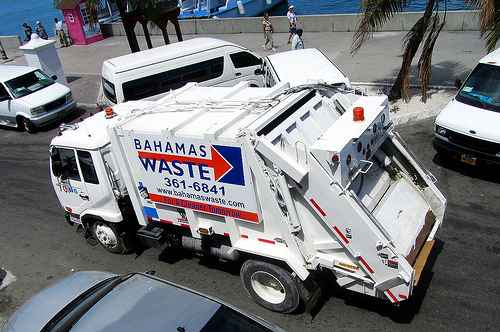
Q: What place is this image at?
A: It is at the street.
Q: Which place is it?
A: It is a street.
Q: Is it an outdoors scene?
A: Yes, it is outdoors.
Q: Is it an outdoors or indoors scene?
A: It is outdoors.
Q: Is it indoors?
A: No, it is outdoors.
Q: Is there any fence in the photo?
A: No, there are no fences.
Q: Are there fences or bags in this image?
A: No, there are no fences or bags.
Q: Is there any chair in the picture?
A: No, there are no chairs.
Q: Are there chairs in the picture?
A: No, there are no chairs.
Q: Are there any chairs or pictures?
A: No, there are no chairs or pictures.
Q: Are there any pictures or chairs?
A: No, there are no chairs or pictures.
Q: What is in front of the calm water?
A: The wall is in front of the water.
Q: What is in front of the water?
A: The wall is in front of the water.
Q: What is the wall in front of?
A: The wall is in front of the water.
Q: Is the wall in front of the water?
A: Yes, the wall is in front of the water.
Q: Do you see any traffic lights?
A: No, there are no traffic lights.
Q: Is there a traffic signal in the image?
A: No, there are no traffic lights.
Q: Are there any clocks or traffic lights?
A: No, there are no traffic lights or clocks.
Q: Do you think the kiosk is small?
A: Yes, the kiosk is small.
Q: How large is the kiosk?
A: The kiosk is small.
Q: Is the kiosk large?
A: No, the kiosk is small.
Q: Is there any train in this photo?
A: No, there are no trains.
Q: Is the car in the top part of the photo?
A: No, the car is in the bottom of the image.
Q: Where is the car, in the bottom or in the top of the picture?
A: The car is in the bottom of the image.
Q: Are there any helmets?
A: No, there are no helmets.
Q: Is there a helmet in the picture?
A: No, there are no helmets.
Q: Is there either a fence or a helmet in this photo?
A: No, there are no helmets or fences.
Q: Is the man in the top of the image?
A: Yes, the man is in the top of the image.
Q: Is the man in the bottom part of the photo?
A: No, the man is in the top of the image.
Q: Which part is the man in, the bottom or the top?
A: The man is in the top of the image.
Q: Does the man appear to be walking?
A: Yes, the man is walking.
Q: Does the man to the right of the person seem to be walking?
A: Yes, the man is walking.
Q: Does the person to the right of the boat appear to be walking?
A: Yes, the man is walking.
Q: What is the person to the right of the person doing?
A: The man is walking.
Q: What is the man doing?
A: The man is walking.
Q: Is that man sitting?
A: No, the man is walking.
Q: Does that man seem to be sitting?
A: No, the man is walking.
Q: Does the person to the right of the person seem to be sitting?
A: No, the man is walking.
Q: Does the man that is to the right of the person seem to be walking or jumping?
A: The man is walking.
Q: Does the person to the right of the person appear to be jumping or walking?
A: The man is walking.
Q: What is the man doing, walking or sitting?
A: The man is walking.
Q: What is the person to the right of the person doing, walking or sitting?
A: The man is walking.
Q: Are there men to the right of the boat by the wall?
A: Yes, there is a man to the right of the boat.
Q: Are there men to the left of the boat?
A: No, the man is to the right of the boat.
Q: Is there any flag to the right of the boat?
A: No, there is a man to the right of the boat.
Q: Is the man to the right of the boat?
A: Yes, the man is to the right of the boat.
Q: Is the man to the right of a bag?
A: No, the man is to the right of the boat.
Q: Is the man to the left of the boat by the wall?
A: No, the man is to the right of the boat.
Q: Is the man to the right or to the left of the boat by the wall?
A: The man is to the right of the boat.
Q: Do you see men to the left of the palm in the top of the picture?
A: Yes, there is a man to the left of the palm.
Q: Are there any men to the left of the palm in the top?
A: Yes, there is a man to the left of the palm.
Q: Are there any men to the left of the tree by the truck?
A: Yes, there is a man to the left of the palm.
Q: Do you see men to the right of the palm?
A: No, the man is to the left of the palm.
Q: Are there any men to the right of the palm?
A: No, the man is to the left of the palm.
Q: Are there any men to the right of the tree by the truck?
A: No, the man is to the left of the palm.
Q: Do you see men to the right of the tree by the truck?
A: No, the man is to the left of the palm.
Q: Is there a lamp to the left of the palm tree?
A: No, there is a man to the left of the palm tree.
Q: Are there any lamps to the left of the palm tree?
A: No, there is a man to the left of the palm tree.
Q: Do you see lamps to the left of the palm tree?
A: No, there is a man to the left of the palm tree.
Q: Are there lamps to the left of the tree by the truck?
A: No, there is a man to the left of the palm tree.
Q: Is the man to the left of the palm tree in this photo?
A: Yes, the man is to the left of the palm tree.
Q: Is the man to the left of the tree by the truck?
A: Yes, the man is to the left of the palm tree.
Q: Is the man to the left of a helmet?
A: No, the man is to the left of the palm tree.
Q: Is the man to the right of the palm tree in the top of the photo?
A: No, the man is to the left of the palm tree.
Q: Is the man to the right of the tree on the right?
A: No, the man is to the left of the palm tree.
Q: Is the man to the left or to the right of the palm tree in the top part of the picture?
A: The man is to the left of the palm.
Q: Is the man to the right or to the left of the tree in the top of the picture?
A: The man is to the left of the palm.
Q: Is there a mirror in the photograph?
A: Yes, there is a mirror.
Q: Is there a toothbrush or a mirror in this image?
A: Yes, there is a mirror.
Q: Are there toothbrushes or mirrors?
A: Yes, there is a mirror.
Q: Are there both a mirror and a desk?
A: No, there is a mirror but no desks.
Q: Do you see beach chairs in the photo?
A: No, there are no beach chairs.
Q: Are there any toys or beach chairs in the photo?
A: No, there are no beach chairs or toys.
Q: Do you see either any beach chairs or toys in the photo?
A: No, there are no beach chairs or toys.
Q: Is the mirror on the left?
A: Yes, the mirror is on the left of the image.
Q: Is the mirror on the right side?
A: No, the mirror is on the left of the image.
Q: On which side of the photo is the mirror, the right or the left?
A: The mirror is on the left of the image.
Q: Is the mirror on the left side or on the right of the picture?
A: The mirror is on the left of the image.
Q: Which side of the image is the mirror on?
A: The mirror is on the left of the image.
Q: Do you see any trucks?
A: Yes, there is a truck.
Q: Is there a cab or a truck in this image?
A: Yes, there is a truck.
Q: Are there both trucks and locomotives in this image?
A: No, there is a truck but no locomotives.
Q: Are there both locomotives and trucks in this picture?
A: No, there is a truck but no locomotives.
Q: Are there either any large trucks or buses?
A: Yes, there is a large truck.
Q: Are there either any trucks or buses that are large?
A: Yes, the truck is large.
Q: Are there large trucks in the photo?
A: Yes, there is a large truck.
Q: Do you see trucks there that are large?
A: Yes, there is a truck that is large.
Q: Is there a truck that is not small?
A: Yes, there is a large truck.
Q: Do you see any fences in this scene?
A: No, there are no fences.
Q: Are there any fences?
A: No, there are no fences.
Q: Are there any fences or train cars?
A: No, there are no fences or train cars.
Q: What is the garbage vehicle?
A: The vehicle is a truck.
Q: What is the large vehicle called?
A: The vehicle is a truck.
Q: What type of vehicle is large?
A: The vehicle is a truck.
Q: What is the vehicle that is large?
A: The vehicle is a truck.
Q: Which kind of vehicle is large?
A: The vehicle is a truck.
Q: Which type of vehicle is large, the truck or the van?
A: The truck is large.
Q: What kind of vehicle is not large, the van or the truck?
A: The van is not large.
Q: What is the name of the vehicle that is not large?
A: The vehicle is a van.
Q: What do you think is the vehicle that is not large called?
A: The vehicle is a van.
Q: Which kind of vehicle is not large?
A: The vehicle is a van.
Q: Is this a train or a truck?
A: This is a truck.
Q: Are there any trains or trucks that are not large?
A: No, there is a truck but it is large.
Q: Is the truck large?
A: Yes, the truck is large.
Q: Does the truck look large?
A: Yes, the truck is large.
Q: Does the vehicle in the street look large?
A: Yes, the truck is large.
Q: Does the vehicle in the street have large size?
A: Yes, the truck is large.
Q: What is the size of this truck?
A: The truck is large.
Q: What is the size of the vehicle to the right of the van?
A: The truck is large.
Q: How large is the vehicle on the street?
A: The truck is large.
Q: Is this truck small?
A: No, the truck is large.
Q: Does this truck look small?
A: No, the truck is large.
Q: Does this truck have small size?
A: No, the truck is large.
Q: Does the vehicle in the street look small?
A: No, the truck is large.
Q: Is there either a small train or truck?
A: No, there is a truck but it is large.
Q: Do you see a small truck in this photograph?
A: No, there is a truck but it is large.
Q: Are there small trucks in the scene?
A: No, there is a truck but it is large.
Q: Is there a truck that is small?
A: No, there is a truck but it is large.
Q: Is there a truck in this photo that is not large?
A: No, there is a truck but it is large.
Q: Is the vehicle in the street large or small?
A: The truck is large.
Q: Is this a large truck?
A: Yes, this is a large truck.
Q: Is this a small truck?
A: No, this is a large truck.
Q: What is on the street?
A: The truck is on the street.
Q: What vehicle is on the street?
A: The vehicle is a truck.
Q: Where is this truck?
A: The truck is on the street.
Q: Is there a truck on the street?
A: Yes, there is a truck on the street.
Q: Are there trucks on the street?
A: Yes, there is a truck on the street.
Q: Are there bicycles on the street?
A: No, there is a truck on the street.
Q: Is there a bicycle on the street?
A: No, there is a truck on the street.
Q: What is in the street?
A: The truck is in the street.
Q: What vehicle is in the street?
A: The vehicle is a truck.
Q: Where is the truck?
A: The truck is in the street.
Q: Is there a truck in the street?
A: Yes, there is a truck in the street.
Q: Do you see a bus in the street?
A: No, there is a truck in the street.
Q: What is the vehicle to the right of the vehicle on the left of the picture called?
A: The vehicle is a truck.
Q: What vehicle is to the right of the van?
A: The vehicle is a truck.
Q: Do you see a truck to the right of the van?
A: Yes, there is a truck to the right of the van.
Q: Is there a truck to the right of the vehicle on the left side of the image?
A: Yes, there is a truck to the right of the van.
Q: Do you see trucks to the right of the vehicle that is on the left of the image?
A: Yes, there is a truck to the right of the van.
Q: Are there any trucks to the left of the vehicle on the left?
A: No, the truck is to the right of the van.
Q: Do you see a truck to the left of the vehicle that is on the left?
A: No, the truck is to the right of the van.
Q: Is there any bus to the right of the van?
A: No, there is a truck to the right of the van.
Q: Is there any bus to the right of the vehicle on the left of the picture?
A: No, there is a truck to the right of the van.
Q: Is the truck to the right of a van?
A: Yes, the truck is to the right of a van.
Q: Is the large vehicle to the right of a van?
A: Yes, the truck is to the right of a van.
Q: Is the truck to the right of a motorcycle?
A: No, the truck is to the right of a van.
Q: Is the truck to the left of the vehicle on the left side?
A: No, the truck is to the right of the van.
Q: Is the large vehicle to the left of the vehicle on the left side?
A: No, the truck is to the right of the van.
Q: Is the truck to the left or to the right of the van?
A: The truck is to the right of the van.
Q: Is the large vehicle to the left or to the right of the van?
A: The truck is to the right of the van.